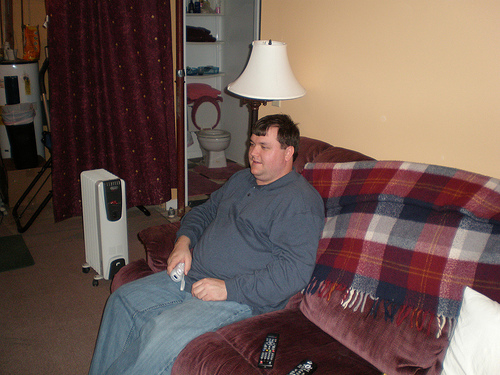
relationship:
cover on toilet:
[188, 92, 224, 130] [186, 94, 248, 181]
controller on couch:
[247, 320, 283, 367] [126, 138, 483, 352]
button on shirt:
[236, 184, 266, 208] [163, 155, 374, 315]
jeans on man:
[79, 265, 275, 370] [58, 110, 369, 365]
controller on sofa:
[258, 334, 280, 369] [113, 94, 475, 373]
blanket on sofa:
[293, 145, 483, 345] [69, 116, 483, 355]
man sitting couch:
[147, 106, 347, 316] [110, 136, 498, 375]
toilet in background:
[188, 89, 241, 179] [88, 11, 484, 127]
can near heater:
[8, 113, 48, 167] [8, 48, 53, 168]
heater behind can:
[1, 59, 68, 174] [7, 96, 40, 166]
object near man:
[69, 165, 153, 282] [80, 103, 364, 363]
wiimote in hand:
[167, 248, 194, 286] [157, 236, 204, 278]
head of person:
[240, 114, 316, 193] [75, 107, 346, 367]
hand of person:
[157, 228, 201, 284] [58, 107, 339, 372]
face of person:
[239, 128, 315, 181] [75, 107, 346, 367]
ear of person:
[280, 133, 306, 169] [58, 107, 339, 372]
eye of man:
[249, 141, 255, 149] [91, 113, 325, 374]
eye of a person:
[250, 140, 271, 154] [216, 113, 341, 247]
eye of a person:
[245, 133, 259, 156] [219, 102, 329, 222]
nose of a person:
[241, 142, 271, 180] [218, 99, 334, 231]